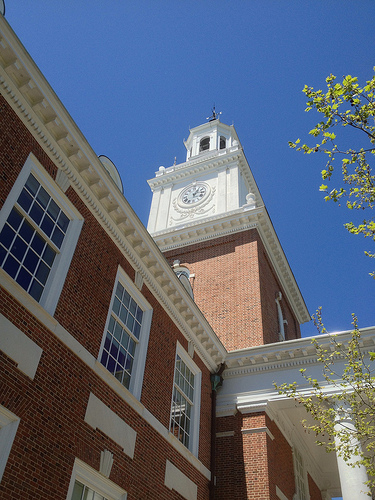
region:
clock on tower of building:
[146, 111, 241, 233]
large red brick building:
[0, 1, 373, 499]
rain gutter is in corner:
[210, 362, 227, 497]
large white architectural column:
[324, 391, 374, 499]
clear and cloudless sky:
[4, 0, 373, 349]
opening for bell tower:
[199, 135, 211, 151]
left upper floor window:
[0, 151, 84, 315]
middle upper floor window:
[94, 264, 154, 400]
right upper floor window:
[167, 338, 202, 462]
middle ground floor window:
[66, 457, 127, 498]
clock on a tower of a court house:
[175, 182, 207, 205]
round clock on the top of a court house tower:
[178, 182, 205, 205]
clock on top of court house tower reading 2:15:
[178, 184, 209, 205]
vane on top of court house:
[205, 98, 221, 125]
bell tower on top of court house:
[171, 120, 253, 156]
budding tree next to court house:
[274, 171, 374, 493]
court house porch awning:
[215, 324, 374, 415]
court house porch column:
[320, 397, 372, 499]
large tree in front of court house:
[269, 172, 374, 499]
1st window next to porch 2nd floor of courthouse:
[165, 337, 207, 461]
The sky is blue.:
[65, 17, 318, 103]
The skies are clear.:
[82, 4, 363, 111]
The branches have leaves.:
[304, 313, 373, 424]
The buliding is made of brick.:
[201, 247, 272, 345]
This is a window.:
[110, 270, 145, 390]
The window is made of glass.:
[6, 238, 56, 299]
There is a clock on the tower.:
[164, 168, 237, 224]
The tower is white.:
[147, 119, 276, 233]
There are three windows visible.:
[14, 150, 212, 444]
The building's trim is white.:
[34, 93, 219, 354]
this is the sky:
[77, 2, 277, 86]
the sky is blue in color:
[94, 8, 217, 52]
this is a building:
[22, 176, 178, 371]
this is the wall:
[20, 385, 84, 463]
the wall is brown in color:
[35, 390, 66, 432]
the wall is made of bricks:
[37, 393, 77, 431]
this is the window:
[112, 293, 136, 358]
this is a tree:
[296, 374, 361, 489]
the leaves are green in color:
[345, 371, 365, 438]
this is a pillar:
[316, 425, 369, 497]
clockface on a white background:
[175, 179, 216, 211]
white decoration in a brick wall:
[81, 389, 135, 458]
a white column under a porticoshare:
[321, 389, 371, 498]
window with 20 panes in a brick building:
[165, 336, 201, 458]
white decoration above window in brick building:
[94, 445, 115, 479]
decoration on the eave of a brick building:
[174, 301, 228, 375]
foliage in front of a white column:
[273, 301, 371, 476]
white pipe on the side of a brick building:
[270, 287, 289, 342]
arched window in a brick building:
[161, 255, 200, 300]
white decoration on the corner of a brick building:
[240, 422, 278, 442]